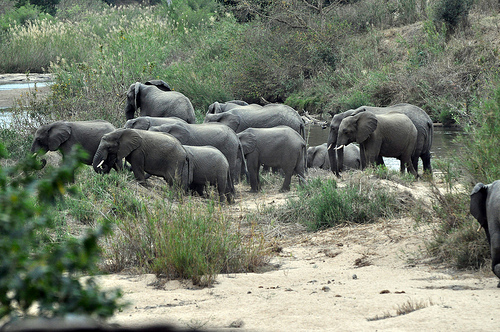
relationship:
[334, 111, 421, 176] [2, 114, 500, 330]
elephant in field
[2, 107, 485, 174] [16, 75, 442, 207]
water beside elephants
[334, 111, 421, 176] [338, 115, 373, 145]
elephant has a head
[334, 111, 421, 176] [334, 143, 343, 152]
elephant has a tusk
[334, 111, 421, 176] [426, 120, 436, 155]
elephant has a tail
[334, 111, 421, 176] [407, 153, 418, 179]
elephant has a leg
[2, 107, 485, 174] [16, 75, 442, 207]
water behind elephants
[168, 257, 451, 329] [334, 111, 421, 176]
sand beside elephant